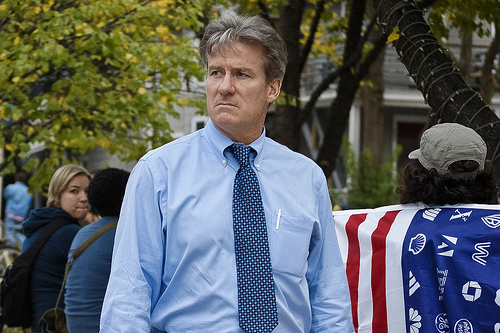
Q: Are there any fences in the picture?
A: No, there are no fences.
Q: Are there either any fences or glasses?
A: No, there are no fences or glasses.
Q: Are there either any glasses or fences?
A: No, there are no fences or glasses.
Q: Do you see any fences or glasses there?
A: No, there are no fences or glasses.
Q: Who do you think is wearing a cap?
A: The man is wearing a cap.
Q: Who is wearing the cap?
A: The man is wearing a cap.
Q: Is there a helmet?
A: No, there are no helmets.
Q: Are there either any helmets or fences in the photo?
A: No, there are no helmets or fences.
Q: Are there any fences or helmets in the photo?
A: No, there are no helmets or fences.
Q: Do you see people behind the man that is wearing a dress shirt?
A: Yes, there is a person behind the man.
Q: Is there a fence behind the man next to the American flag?
A: No, there is a person behind the man.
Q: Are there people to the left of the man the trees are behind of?
A: Yes, there is a person to the left of the man.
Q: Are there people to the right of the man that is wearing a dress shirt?
A: No, the person is to the left of the man.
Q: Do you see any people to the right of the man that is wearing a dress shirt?
A: No, the person is to the left of the man.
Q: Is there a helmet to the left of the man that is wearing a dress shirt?
A: No, there is a person to the left of the man.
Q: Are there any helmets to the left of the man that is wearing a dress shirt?
A: No, there is a person to the left of the man.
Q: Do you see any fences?
A: No, there are no fences.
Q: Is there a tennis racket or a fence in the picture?
A: No, there are no fences or rackets.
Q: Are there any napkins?
A: No, there are no napkins.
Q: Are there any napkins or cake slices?
A: No, there are no napkins or cake slices.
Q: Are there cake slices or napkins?
A: No, there are no napkins or cake slices.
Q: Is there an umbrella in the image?
A: No, there are no umbrellas.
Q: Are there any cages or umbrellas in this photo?
A: No, there are no umbrellas or cages.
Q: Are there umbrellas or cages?
A: No, there are no umbrellas or cages.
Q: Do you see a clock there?
A: No, there are no clocks.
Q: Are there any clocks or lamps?
A: No, there are no clocks or lamps.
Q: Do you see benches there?
A: No, there are no benches.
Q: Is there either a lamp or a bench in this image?
A: No, there are no benches or lamps.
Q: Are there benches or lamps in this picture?
A: No, there are no benches or lamps.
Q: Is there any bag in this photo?
A: Yes, there is a bag.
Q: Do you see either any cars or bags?
A: Yes, there is a bag.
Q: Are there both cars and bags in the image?
A: No, there is a bag but no cars.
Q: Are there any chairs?
A: No, there are no chairs.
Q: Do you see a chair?
A: No, there are no chairs.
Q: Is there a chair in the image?
A: No, there are no chairs.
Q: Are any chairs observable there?
A: No, there are no chairs.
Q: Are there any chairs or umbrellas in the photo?
A: No, there are no chairs or umbrellas.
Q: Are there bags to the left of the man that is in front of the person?
A: Yes, there is a bag to the left of the man.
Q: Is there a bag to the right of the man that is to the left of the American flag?
A: No, the bag is to the left of the man.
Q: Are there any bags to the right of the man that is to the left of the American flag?
A: No, the bag is to the left of the man.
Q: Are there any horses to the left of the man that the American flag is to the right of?
A: No, there is a bag to the left of the man.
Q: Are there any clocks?
A: No, there are no clocks.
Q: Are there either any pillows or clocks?
A: No, there are no clocks or pillows.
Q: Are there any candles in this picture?
A: No, there are no candles.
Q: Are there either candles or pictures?
A: No, there are no candles or pictures.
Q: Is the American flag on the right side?
A: Yes, the American flag is on the right of the image.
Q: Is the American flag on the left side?
A: No, the American flag is on the right of the image.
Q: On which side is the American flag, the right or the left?
A: The American flag is on the right of the image.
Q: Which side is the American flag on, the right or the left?
A: The American flag is on the right of the image.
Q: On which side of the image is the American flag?
A: The American flag is on the right of the image.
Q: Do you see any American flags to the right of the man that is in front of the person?
A: Yes, there is an American flag to the right of the man.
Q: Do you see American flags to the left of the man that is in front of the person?
A: No, the American flag is to the right of the man.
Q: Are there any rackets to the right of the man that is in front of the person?
A: No, there is an American flag to the right of the man.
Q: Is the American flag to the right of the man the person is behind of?
A: Yes, the American flag is to the right of the man.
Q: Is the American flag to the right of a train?
A: No, the American flag is to the right of the man.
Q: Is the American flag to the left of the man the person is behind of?
A: No, the American flag is to the right of the man.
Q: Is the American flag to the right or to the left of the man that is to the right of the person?
A: The American flag is to the right of the man.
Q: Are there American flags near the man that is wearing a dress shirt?
A: Yes, there is an American flag near the man.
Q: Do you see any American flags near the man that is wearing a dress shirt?
A: Yes, there is an American flag near the man.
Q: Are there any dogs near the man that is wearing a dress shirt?
A: No, there is an American flag near the man.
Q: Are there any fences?
A: No, there are no fences.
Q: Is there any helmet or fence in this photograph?
A: No, there are no fences or helmets.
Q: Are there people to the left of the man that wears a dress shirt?
A: Yes, there is a person to the left of the man.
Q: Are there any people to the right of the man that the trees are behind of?
A: No, the person is to the left of the man.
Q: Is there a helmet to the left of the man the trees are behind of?
A: No, there is a person to the left of the man.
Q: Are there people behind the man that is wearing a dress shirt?
A: Yes, there is a person behind the man.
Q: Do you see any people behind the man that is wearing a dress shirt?
A: Yes, there is a person behind the man.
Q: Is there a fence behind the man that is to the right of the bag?
A: No, there is a person behind the man.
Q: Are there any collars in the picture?
A: Yes, there is a collar.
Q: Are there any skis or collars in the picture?
A: Yes, there is a collar.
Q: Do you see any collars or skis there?
A: Yes, there is a collar.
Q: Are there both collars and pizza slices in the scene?
A: No, there is a collar but no pizza slices.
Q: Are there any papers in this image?
A: No, there are no papers.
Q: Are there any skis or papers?
A: No, there are no papers or skis.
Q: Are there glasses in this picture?
A: No, there are no glasses.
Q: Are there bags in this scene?
A: Yes, there is a bag.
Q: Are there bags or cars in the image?
A: Yes, there is a bag.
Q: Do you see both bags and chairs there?
A: No, there is a bag but no chairs.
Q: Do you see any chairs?
A: No, there are no chairs.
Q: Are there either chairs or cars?
A: No, there are no chairs or cars.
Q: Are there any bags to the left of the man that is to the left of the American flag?
A: Yes, there is a bag to the left of the man.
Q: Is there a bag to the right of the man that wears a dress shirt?
A: No, the bag is to the left of the man.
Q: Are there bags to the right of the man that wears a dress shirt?
A: No, the bag is to the left of the man.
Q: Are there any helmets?
A: No, there are no helmets.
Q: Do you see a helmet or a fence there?
A: No, there are no helmets or fences.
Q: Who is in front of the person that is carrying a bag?
A: The man is in front of the person.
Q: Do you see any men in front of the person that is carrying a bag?
A: Yes, there is a man in front of the person.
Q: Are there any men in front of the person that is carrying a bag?
A: Yes, there is a man in front of the person.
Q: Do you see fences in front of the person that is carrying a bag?
A: No, there is a man in front of the person.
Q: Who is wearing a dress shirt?
A: The man is wearing a dress shirt.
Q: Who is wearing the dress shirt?
A: The man is wearing a dress shirt.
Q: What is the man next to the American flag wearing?
A: The man is wearing a dress shirt.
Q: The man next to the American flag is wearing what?
A: The man is wearing a dress shirt.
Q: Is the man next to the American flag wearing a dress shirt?
A: Yes, the man is wearing a dress shirt.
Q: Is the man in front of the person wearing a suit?
A: No, the man is wearing a dress shirt.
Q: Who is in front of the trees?
A: The man is in front of the trees.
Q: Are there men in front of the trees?
A: Yes, there is a man in front of the trees.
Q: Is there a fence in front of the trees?
A: No, there is a man in front of the trees.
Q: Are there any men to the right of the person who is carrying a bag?
A: Yes, there is a man to the right of the person.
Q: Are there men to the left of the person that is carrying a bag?
A: No, the man is to the right of the person.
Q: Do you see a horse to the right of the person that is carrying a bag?
A: No, there is a man to the right of the person.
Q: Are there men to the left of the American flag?
A: Yes, there is a man to the left of the American flag.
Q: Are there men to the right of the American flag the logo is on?
A: No, the man is to the left of the American flag.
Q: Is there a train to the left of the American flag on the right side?
A: No, there is a man to the left of the American flag.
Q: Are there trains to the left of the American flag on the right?
A: No, there is a man to the left of the American flag.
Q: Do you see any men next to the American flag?
A: Yes, there is a man next to the American flag.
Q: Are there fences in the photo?
A: No, there are no fences.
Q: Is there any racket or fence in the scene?
A: No, there are no fences or rackets.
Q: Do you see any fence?
A: No, there are no fences.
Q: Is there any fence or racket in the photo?
A: No, there are no fences or rackets.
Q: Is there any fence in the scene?
A: No, there are no fences.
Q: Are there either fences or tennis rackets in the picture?
A: No, there are no fences or tennis rackets.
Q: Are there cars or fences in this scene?
A: No, there are no fences or cars.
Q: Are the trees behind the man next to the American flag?
A: Yes, the trees are behind the man.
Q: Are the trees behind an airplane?
A: No, the trees are behind the man.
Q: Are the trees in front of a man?
A: No, the trees are behind a man.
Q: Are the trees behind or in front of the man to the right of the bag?
A: The trees are behind the man.